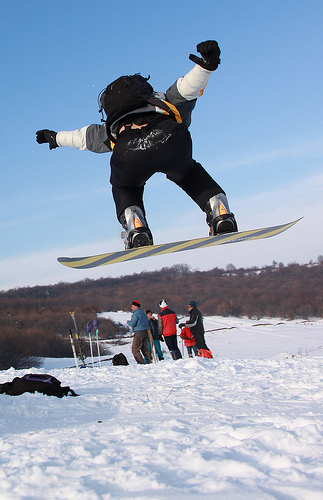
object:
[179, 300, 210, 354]
person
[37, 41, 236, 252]
snow boarder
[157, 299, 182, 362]
person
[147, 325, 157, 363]
ski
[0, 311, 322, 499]
ground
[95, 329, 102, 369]
pole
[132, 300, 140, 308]
cap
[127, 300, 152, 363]
person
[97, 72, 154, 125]
back pack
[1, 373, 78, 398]
bag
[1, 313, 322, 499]
snow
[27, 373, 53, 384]
stripes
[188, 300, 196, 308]
cap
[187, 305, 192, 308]
goggles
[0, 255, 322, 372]
woods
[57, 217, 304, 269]
snowboard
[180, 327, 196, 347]
coat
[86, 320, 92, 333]
gloves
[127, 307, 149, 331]
coat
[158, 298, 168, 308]
cap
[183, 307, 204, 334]
coat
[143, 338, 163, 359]
pants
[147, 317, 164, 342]
coat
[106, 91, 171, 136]
back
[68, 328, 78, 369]
pole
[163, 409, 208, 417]
tracks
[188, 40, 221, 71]
gloves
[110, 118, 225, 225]
pants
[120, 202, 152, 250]
shoes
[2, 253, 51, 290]
clouds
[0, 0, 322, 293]
sky